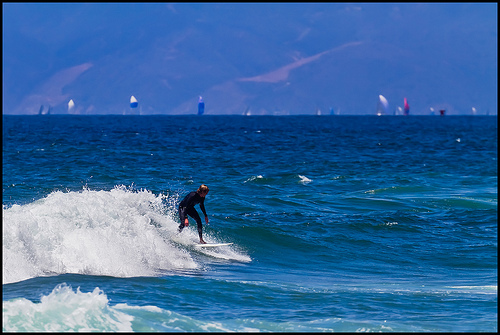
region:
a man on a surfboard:
[79, 102, 326, 290]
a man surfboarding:
[132, 143, 263, 273]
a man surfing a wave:
[110, 116, 354, 324]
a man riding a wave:
[134, 145, 271, 292]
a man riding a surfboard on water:
[100, 132, 377, 333]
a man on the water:
[101, 136, 364, 333]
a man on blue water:
[118, 166, 322, 333]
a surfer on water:
[127, 130, 322, 291]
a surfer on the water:
[143, 155, 378, 330]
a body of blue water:
[35, 111, 496, 311]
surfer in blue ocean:
[17, 118, 487, 296]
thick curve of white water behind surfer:
[2, 161, 248, 286]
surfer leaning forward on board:
[175, 175, 231, 245]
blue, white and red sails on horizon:
[5, 85, 490, 120]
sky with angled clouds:
[6, 5, 482, 105]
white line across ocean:
[157, 255, 492, 301]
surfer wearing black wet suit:
[172, 180, 207, 245]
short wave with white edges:
[240, 160, 315, 190]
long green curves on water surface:
[347, 180, 492, 211]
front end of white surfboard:
[190, 237, 236, 250]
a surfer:
[159, 172, 247, 261]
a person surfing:
[153, 167, 252, 268]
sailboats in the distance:
[18, 75, 498, 127]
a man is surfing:
[127, 176, 246, 261]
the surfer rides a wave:
[32, 177, 271, 278]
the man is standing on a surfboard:
[128, 172, 249, 259]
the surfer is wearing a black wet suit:
[138, 169, 245, 262]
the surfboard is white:
[149, 233, 239, 262]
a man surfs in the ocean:
[43, 125, 487, 325]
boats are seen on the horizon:
[24, 87, 498, 124]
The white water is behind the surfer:
[22, 190, 142, 265]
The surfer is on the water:
[156, 160, 236, 252]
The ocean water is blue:
[51, 117, 431, 177]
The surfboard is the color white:
[180, 236, 237, 253]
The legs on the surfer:
[170, 218, 210, 245]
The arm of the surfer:
[179, 193, 198, 228]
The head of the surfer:
[192, 183, 212, 202]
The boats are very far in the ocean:
[23, 78, 493, 133]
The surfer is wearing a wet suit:
[168, 182, 214, 244]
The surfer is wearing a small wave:
[58, 163, 264, 265]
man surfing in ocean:
[164, 169, 227, 248]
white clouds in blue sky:
[21, 14, 61, 45]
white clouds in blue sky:
[27, 63, 67, 90]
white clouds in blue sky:
[62, 11, 132, 53]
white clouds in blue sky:
[84, 54, 147, 79]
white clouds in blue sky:
[135, 10, 223, 55]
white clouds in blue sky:
[217, 56, 292, 92]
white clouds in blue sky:
[251, 21, 342, 86]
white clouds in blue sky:
[366, 28, 476, 74]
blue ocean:
[278, 218, 411, 295]